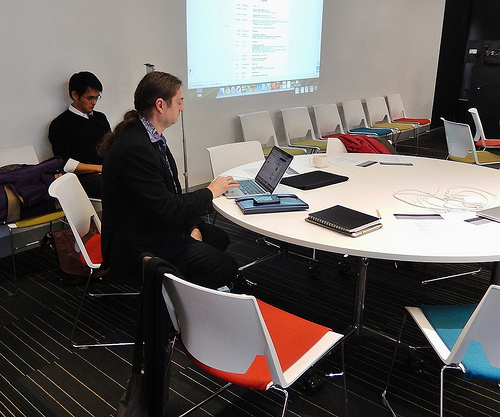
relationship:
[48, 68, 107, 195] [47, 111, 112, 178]
man wearing sweater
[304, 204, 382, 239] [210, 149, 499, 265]
notebooks are on top of table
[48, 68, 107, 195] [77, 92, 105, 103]
man wearing glasses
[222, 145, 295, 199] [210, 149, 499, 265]
laptop on top of table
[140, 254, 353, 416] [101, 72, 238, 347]
chair next to man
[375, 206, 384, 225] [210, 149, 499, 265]
pencil on top of table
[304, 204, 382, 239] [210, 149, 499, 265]
notebooks on top of table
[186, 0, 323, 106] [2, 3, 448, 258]
projection against wall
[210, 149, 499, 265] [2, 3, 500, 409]
table in room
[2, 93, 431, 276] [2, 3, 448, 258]
chairs against wall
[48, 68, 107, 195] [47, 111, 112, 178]
man has sweater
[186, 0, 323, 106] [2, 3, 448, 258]
projection on wall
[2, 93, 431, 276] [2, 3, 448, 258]
chairs on wall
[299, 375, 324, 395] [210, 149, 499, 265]
wheels attached to table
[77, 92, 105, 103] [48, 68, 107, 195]
glasses worn by man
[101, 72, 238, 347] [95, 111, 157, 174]
man has pony tail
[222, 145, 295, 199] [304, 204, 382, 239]
laptop beside notebooks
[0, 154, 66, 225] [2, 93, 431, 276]
bag across chairs